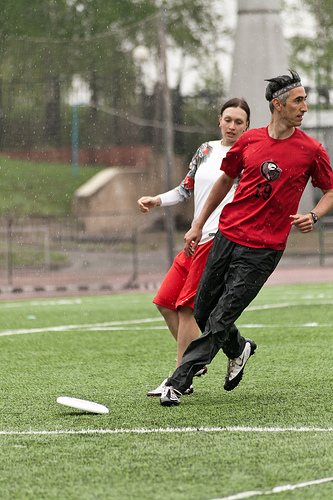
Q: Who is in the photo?
A: Man and woman.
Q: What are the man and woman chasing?
A: A Frisbee.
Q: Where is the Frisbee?
A: On the ground.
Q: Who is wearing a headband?
A: The man.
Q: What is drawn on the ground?
A: White lines.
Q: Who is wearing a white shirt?
A: The woman.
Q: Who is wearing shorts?
A: The woman.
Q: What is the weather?
A: Rain.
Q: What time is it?
A: Afternoon.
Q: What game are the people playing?
A: Frisbee.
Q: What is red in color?
A: The man's shirt.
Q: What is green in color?
A: The grass.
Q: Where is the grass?
A: Under the people.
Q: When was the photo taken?
A: During the daytime.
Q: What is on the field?
A: White lines.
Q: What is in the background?
A: Trees.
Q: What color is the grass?
A: Green.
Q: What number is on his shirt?
A: 19.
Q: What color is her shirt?
A: White.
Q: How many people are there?
A: Two.